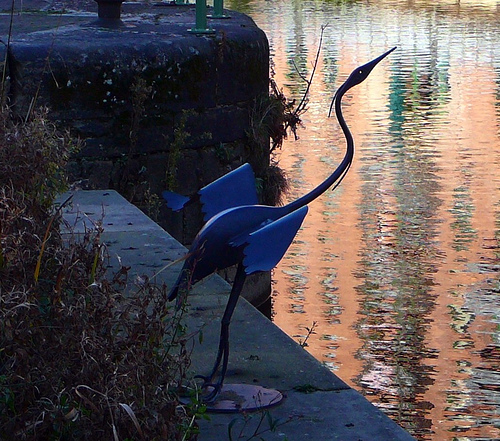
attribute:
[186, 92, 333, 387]
heron — blue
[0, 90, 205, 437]
brush — green, brown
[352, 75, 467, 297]
reflections — pink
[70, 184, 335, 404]
ledge — green, blue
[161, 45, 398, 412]
bird — sculpture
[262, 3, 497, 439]
water — rippled, silver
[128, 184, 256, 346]
ledge — concrete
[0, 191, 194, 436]
bush — tall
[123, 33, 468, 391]
bird — blue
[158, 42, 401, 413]
statue — blue, metal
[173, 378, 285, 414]
base — round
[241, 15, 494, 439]
reflection — pink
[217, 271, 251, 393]
leg — metal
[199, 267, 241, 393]
leg — metal